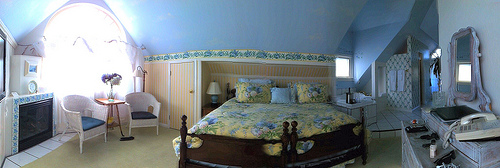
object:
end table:
[201, 102, 222, 118]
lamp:
[206, 81, 222, 108]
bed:
[171, 78, 368, 168]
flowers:
[171, 82, 368, 156]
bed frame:
[178, 82, 368, 168]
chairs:
[57, 91, 162, 154]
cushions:
[130, 111, 157, 119]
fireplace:
[18, 97, 54, 153]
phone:
[441, 112, 500, 142]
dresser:
[399, 27, 499, 168]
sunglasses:
[431, 149, 455, 166]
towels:
[389, 70, 407, 92]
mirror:
[450, 25, 481, 101]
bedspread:
[171, 96, 371, 159]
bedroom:
[0, 0, 497, 168]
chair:
[123, 92, 161, 136]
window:
[39, 2, 142, 102]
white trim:
[10, 91, 59, 156]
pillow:
[233, 81, 272, 102]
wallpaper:
[140, 49, 336, 67]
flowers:
[101, 72, 122, 102]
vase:
[108, 89, 115, 102]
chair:
[57, 95, 109, 154]